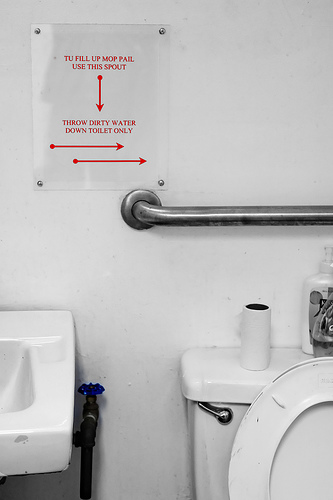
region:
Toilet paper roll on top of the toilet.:
[237, 307, 256, 359]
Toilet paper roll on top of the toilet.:
[7, 340, 8, 383]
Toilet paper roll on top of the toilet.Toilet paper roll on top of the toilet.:
[91, 397, 101, 467]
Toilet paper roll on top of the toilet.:
[162, 424, 310, 445]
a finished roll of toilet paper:
[226, 297, 276, 376]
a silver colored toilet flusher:
[186, 387, 237, 435]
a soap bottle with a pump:
[297, 236, 331, 361]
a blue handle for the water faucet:
[76, 378, 115, 429]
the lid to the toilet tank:
[171, 343, 260, 409]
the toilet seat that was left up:
[242, 370, 332, 484]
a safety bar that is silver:
[109, 188, 328, 255]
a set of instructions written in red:
[19, 5, 188, 187]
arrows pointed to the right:
[42, 139, 148, 175]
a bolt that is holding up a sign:
[18, 174, 54, 194]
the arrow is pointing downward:
[90, 74, 108, 113]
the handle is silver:
[195, 398, 234, 427]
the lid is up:
[259, 363, 331, 410]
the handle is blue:
[78, 379, 107, 401]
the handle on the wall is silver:
[213, 202, 256, 232]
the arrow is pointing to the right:
[94, 137, 129, 154]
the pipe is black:
[76, 457, 97, 490]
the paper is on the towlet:
[231, 294, 275, 377]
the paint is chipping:
[8, 433, 33, 445]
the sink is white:
[28, 325, 59, 364]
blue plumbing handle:
[76, 382, 104, 395]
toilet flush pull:
[197, 403, 231, 424]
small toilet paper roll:
[243, 303, 270, 371]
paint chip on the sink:
[14, 435, 30, 443]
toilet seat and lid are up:
[226, 358, 332, 498]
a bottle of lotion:
[301, 247, 330, 353]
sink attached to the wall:
[0, 309, 74, 478]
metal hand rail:
[120, 189, 330, 230]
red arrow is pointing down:
[95, 75, 103, 111]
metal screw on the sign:
[159, 26, 164, 33]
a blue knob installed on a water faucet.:
[76, 376, 106, 412]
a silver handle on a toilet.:
[156, 383, 236, 441]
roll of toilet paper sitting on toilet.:
[237, 305, 271, 382]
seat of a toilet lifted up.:
[249, 384, 330, 496]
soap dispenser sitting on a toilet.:
[298, 243, 332, 336]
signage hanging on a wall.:
[44, 36, 170, 222]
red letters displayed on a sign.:
[38, 42, 177, 174]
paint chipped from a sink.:
[5, 429, 43, 458]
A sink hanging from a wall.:
[1, 305, 83, 473]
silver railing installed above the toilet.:
[148, 192, 321, 259]